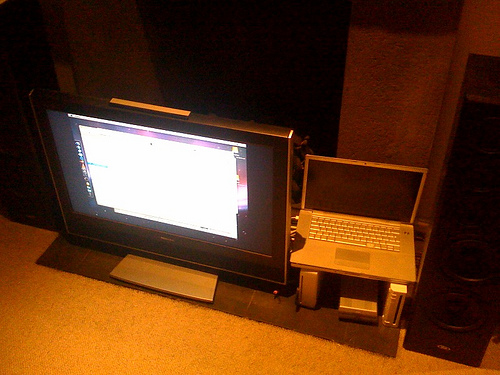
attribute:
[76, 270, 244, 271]
base — white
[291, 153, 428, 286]
laptop — gray, white, silver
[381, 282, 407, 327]
hard drive — white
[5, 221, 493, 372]
carpet — white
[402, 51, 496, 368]
speaker — tall, black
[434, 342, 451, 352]
logo — gray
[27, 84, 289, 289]
rim — metal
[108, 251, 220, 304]
base — plastic, silver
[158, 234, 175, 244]
logo — gray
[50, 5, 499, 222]
wall — grey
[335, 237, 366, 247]
key — gray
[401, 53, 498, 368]
tower — black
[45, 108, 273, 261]
monitor — large, lcd